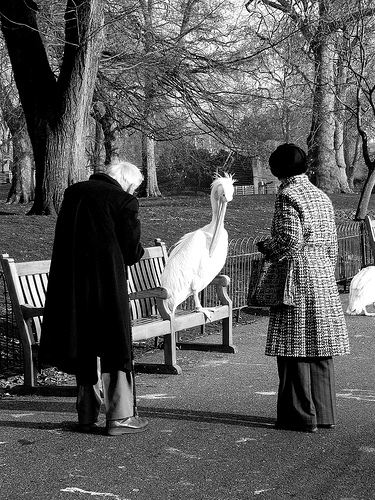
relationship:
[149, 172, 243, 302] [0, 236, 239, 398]
bird on  a bench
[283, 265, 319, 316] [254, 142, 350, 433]
coat on a people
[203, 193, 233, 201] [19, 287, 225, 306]
bird on bench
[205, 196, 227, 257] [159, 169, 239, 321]
beak on a bird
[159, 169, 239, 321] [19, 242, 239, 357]
bird who stands on a bench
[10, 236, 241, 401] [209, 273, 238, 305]
bench with armrest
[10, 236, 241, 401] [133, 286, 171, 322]
bench with armrest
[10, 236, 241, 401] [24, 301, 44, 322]
bench with armrest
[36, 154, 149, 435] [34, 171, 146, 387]
man wearing coat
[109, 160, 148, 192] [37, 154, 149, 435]
hair of man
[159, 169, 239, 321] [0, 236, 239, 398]
bird standing on a bench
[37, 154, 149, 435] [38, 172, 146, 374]
man in coat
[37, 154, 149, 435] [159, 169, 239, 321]
man standing by a bird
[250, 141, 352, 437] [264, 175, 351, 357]
people in coat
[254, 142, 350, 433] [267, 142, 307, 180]
people in hat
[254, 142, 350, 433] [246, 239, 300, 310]
people holding bag